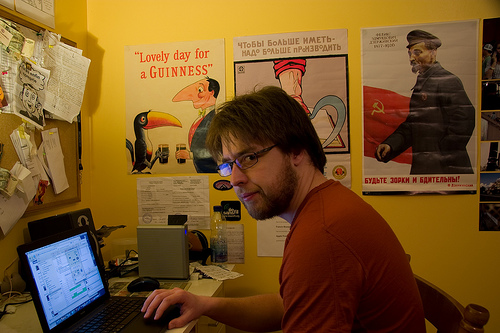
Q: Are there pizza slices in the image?
A: No, there are no pizza slices.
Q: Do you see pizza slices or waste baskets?
A: No, there are no pizza slices or waste baskets.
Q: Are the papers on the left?
A: Yes, the papers are on the left of the image.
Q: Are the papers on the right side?
A: No, the papers are on the left of the image.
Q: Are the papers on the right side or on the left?
A: The papers are on the left of the image.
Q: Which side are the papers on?
A: The papers are on the left of the image.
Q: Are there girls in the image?
A: No, there are no girls.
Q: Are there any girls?
A: No, there are no girls.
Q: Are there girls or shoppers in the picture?
A: No, there are no girls or shoppers.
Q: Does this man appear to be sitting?
A: Yes, the man is sitting.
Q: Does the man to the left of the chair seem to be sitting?
A: Yes, the man is sitting.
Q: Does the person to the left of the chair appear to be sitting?
A: Yes, the man is sitting.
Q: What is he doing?
A: The man is sitting.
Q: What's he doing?
A: The man is sitting.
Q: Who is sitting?
A: The man is sitting.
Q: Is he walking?
A: No, the man is sitting.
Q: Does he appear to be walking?
A: No, the man is sitting.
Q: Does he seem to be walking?
A: No, the man is sitting.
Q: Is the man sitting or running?
A: The man is sitting.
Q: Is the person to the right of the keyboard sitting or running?
A: The man is sitting.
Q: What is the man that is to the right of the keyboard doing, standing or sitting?
A: The man is sitting.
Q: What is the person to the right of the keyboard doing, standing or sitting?
A: The man is sitting.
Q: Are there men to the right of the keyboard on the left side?
A: Yes, there is a man to the right of the keyboard.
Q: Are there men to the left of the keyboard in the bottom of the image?
A: No, the man is to the right of the keyboard.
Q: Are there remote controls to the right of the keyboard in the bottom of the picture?
A: No, there is a man to the right of the keyboard.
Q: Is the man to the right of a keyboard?
A: Yes, the man is to the right of a keyboard.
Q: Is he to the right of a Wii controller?
A: No, the man is to the right of a keyboard.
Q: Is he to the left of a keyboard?
A: No, the man is to the right of a keyboard.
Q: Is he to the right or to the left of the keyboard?
A: The man is to the right of the keyboard.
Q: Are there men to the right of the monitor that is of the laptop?
A: Yes, there is a man to the right of the monitor.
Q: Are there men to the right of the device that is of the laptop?
A: Yes, there is a man to the right of the monitor.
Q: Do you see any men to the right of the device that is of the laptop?
A: Yes, there is a man to the right of the monitor.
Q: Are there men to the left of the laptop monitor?
A: No, the man is to the right of the monitor.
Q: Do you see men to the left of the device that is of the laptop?
A: No, the man is to the right of the monitor.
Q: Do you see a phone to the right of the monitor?
A: No, there is a man to the right of the monitor.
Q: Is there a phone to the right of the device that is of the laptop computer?
A: No, there is a man to the right of the monitor.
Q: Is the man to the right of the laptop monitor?
A: Yes, the man is to the right of the monitor.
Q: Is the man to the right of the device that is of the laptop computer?
A: Yes, the man is to the right of the monitor.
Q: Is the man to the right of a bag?
A: No, the man is to the right of the monitor.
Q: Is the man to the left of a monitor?
A: No, the man is to the right of a monitor.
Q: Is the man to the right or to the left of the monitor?
A: The man is to the right of the monitor.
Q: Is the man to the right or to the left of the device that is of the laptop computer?
A: The man is to the right of the monitor.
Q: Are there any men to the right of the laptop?
A: Yes, there is a man to the right of the laptop.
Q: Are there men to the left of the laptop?
A: No, the man is to the right of the laptop.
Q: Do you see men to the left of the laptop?
A: No, the man is to the right of the laptop.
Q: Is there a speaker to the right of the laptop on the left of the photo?
A: No, there is a man to the right of the laptop.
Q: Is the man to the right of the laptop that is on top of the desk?
A: Yes, the man is to the right of the laptop.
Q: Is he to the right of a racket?
A: No, the man is to the right of the laptop.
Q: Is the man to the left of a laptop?
A: No, the man is to the right of a laptop.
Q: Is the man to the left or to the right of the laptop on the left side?
A: The man is to the right of the laptop.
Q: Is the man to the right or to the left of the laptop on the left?
A: The man is to the right of the laptop.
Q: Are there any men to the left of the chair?
A: Yes, there is a man to the left of the chair.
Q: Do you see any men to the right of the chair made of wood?
A: No, the man is to the left of the chair.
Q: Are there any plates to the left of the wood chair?
A: No, there is a man to the left of the chair.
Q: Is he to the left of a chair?
A: Yes, the man is to the left of a chair.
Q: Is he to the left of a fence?
A: No, the man is to the left of a chair.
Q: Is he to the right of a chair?
A: No, the man is to the left of a chair.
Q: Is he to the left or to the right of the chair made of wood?
A: The man is to the left of the chair.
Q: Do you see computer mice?
A: Yes, there is a computer mouse.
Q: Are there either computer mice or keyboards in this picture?
A: Yes, there is a computer mouse.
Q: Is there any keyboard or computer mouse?
A: Yes, there is a computer mouse.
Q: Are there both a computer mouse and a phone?
A: No, there is a computer mouse but no phones.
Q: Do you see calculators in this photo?
A: No, there are no calculators.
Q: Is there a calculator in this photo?
A: No, there are no calculators.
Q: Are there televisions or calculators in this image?
A: No, there are no calculators or televisions.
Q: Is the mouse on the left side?
A: Yes, the mouse is on the left of the image.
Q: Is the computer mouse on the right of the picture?
A: No, the computer mouse is on the left of the image.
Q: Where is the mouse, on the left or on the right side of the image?
A: The mouse is on the left of the image.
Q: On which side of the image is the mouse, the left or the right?
A: The mouse is on the left of the image.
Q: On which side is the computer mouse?
A: The computer mouse is on the left of the image.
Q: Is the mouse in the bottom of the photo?
A: Yes, the mouse is in the bottom of the image.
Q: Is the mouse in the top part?
A: No, the mouse is in the bottom of the image.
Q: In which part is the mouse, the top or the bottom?
A: The mouse is in the bottom of the image.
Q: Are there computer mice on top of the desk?
A: Yes, there is a computer mouse on top of the desk.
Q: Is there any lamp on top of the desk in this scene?
A: No, there is a computer mouse on top of the desk.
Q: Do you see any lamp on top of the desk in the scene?
A: No, there is a computer mouse on top of the desk.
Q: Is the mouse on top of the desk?
A: Yes, the mouse is on top of the desk.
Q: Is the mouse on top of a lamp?
A: No, the mouse is on top of the desk.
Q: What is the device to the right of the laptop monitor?
A: The device is a computer mouse.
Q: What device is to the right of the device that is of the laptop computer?
A: The device is a computer mouse.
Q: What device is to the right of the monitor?
A: The device is a computer mouse.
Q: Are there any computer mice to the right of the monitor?
A: Yes, there is a computer mouse to the right of the monitor.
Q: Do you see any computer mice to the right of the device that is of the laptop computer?
A: Yes, there is a computer mouse to the right of the monitor.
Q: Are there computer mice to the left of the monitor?
A: No, the computer mouse is to the right of the monitor.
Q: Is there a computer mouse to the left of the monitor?
A: No, the computer mouse is to the right of the monitor.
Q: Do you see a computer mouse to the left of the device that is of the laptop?
A: No, the computer mouse is to the right of the monitor.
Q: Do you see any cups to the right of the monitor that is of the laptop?
A: No, there is a computer mouse to the right of the monitor.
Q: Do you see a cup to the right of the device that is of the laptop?
A: No, there is a computer mouse to the right of the monitor.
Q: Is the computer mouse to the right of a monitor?
A: Yes, the computer mouse is to the right of a monitor.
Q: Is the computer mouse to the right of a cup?
A: No, the computer mouse is to the right of a monitor.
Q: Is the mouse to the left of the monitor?
A: No, the mouse is to the right of the monitor.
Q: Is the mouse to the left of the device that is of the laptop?
A: No, the mouse is to the right of the monitor.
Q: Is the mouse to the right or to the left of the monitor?
A: The mouse is to the right of the monitor.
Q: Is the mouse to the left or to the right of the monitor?
A: The mouse is to the right of the monitor.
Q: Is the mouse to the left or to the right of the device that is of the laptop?
A: The mouse is to the right of the monitor.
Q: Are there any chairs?
A: Yes, there is a chair.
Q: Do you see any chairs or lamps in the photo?
A: Yes, there is a chair.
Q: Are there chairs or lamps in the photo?
A: Yes, there is a chair.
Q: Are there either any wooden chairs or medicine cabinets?
A: Yes, there is a wood chair.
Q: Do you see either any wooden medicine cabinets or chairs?
A: Yes, there is a wood chair.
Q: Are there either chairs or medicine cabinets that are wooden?
A: Yes, the chair is wooden.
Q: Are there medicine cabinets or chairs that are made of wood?
A: Yes, the chair is made of wood.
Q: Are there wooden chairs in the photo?
A: Yes, there is a wood chair.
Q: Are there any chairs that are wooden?
A: Yes, there is a chair that is wooden.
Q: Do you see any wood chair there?
A: Yes, there is a chair that is made of wood.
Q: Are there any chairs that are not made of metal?
A: Yes, there is a chair that is made of wood.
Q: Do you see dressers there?
A: No, there are no dressers.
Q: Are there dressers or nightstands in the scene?
A: No, there are no dressers or nightstands.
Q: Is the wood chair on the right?
A: Yes, the chair is on the right of the image.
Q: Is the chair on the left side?
A: No, the chair is on the right of the image.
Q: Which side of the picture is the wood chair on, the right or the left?
A: The chair is on the right of the image.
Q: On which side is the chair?
A: The chair is on the right of the image.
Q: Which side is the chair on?
A: The chair is on the right of the image.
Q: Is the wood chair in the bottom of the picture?
A: Yes, the chair is in the bottom of the image.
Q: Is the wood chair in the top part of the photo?
A: No, the chair is in the bottom of the image.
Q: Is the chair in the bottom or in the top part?
A: The chair is in the bottom of the image.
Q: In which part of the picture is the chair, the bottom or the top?
A: The chair is in the bottom of the image.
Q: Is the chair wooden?
A: Yes, the chair is wooden.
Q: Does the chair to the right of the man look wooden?
A: Yes, the chair is wooden.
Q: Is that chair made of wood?
A: Yes, the chair is made of wood.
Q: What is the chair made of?
A: The chair is made of wood.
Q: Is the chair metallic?
A: No, the chair is wooden.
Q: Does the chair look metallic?
A: No, the chair is wooden.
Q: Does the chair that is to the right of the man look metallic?
A: No, the chair is wooden.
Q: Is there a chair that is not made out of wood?
A: No, there is a chair but it is made of wood.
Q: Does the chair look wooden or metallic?
A: The chair is wooden.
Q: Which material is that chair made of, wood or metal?
A: The chair is made of wood.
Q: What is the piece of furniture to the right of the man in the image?
A: The piece of furniture is a chair.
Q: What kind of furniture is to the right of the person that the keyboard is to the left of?
A: The piece of furniture is a chair.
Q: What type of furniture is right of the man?
A: The piece of furniture is a chair.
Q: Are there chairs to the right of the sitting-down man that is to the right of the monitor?
A: Yes, there is a chair to the right of the man.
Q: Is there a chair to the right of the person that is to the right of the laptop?
A: Yes, there is a chair to the right of the man.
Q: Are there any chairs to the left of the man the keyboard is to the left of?
A: No, the chair is to the right of the man.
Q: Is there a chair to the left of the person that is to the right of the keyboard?
A: No, the chair is to the right of the man.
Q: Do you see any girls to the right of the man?
A: No, there is a chair to the right of the man.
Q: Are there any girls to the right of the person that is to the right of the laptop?
A: No, there is a chair to the right of the man.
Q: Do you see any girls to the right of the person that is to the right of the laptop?
A: No, there is a chair to the right of the man.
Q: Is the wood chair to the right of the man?
A: Yes, the chair is to the right of the man.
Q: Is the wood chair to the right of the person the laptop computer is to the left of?
A: Yes, the chair is to the right of the man.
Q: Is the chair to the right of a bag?
A: No, the chair is to the right of the man.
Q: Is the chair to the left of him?
A: No, the chair is to the right of a man.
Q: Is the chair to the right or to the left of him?
A: The chair is to the right of the man.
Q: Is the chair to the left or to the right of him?
A: The chair is to the right of the man.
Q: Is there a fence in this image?
A: No, there are no fences.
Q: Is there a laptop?
A: Yes, there is a laptop.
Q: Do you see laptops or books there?
A: Yes, there is a laptop.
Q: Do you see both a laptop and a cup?
A: No, there is a laptop but no cups.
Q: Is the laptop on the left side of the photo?
A: Yes, the laptop is on the left of the image.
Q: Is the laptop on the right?
A: No, the laptop is on the left of the image.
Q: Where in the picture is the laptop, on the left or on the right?
A: The laptop is on the left of the image.